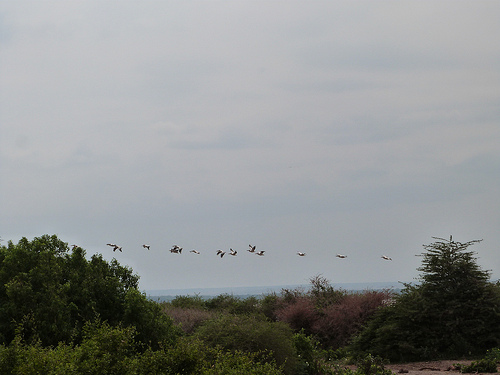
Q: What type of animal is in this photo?
A: Birds.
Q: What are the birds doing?
A: Flying.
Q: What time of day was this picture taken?
A: Daytime.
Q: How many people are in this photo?
A: None.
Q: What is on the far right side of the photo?
A: A tree.